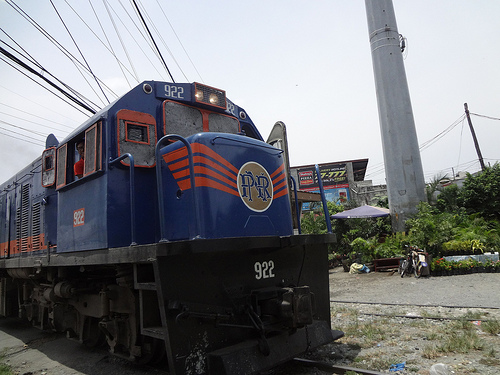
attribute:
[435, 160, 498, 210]
trees — green, leafy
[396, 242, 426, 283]
bicycle — empty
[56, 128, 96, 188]
windows — open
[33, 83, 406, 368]
train — red and blue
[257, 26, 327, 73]
clouds — white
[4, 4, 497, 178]
sky — blue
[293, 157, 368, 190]
billboard — large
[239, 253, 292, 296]
number — white and red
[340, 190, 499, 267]
plants — green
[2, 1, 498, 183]
clouds — blue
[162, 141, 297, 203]
lines — red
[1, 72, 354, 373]
train — blue and orange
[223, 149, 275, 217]
logo — gold and white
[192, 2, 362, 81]
sky — blue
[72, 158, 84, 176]
shirt — red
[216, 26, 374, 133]
clouds — white